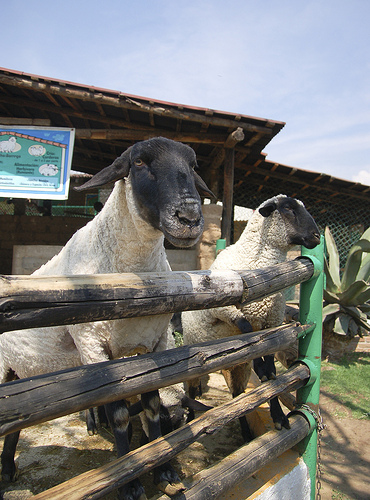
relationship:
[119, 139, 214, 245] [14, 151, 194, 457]
face on sheep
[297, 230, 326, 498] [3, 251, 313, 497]
green post on fence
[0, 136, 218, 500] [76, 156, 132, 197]
sheep has ear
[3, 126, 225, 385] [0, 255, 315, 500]
sheep on fence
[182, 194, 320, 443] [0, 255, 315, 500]
sheep on fence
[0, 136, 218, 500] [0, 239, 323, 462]
sheep in fence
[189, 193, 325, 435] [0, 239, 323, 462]
sheep in fence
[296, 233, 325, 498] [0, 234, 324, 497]
green post in fence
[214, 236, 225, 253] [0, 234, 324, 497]
post in fence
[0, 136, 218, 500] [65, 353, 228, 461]
sheep by wood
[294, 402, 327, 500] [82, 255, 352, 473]
chain on bar holder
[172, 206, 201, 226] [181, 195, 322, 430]
nostrils on sheep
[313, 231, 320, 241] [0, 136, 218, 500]
nostrils on sheep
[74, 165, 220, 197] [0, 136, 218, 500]
ears on sheep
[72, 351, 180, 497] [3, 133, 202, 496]
legs on sheep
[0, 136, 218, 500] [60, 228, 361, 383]
sheep in fence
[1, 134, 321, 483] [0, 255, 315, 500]
sheep in fence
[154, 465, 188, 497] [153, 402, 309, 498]
foot on pole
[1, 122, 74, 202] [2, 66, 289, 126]
sign on roof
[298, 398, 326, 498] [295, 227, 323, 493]
chain on pole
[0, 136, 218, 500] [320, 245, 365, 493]
sheep by fence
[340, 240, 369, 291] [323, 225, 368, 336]
leaf on plant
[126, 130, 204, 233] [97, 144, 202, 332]
face on sheep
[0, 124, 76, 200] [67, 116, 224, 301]
sign behind sheep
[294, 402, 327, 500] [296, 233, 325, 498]
chain on green post